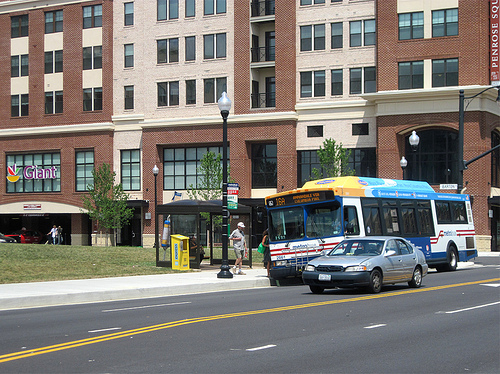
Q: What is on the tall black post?
A: Lamps.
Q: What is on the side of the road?
A: A bus.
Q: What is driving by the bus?
A: A small car.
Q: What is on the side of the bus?
A: A black bus stop.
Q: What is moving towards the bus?
A: A man.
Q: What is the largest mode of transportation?
A: Bus.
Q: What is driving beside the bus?
A: Car.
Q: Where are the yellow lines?
A: Street.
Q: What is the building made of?
A: Brick.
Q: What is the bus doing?
A: Parked.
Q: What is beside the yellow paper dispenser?
A: Bus stop.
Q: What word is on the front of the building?
A: Giant.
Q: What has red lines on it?
A: Bus.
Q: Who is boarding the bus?
A: A woman.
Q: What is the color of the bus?
A: White and blue.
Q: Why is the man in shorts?
A: It's hot.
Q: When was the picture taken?
A: During the day.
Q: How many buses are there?
A: 1.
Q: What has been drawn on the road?
A: Lines.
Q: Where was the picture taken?
A: On a city street.